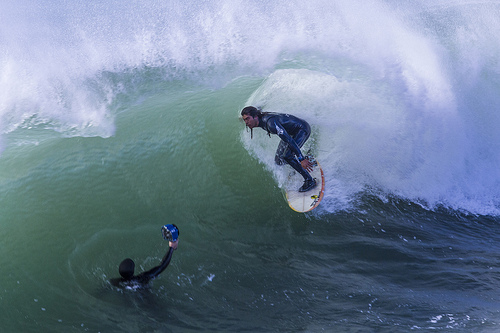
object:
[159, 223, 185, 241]
camera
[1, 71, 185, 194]
water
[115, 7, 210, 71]
splash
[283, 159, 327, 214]
surfboard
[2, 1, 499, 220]
wave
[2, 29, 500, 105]
crest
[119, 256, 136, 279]
head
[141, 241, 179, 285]
arm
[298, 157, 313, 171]
hand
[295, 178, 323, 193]
foot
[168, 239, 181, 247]
hand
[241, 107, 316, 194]
person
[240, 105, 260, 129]
head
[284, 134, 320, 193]
leg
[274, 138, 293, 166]
leg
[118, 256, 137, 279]
hair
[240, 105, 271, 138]
hair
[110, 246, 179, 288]
wetsuit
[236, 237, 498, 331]
water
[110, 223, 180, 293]
people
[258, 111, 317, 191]
bodysuit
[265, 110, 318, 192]
suit